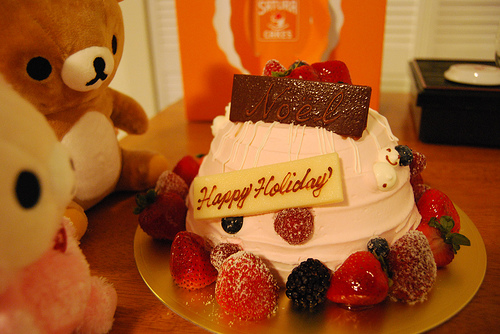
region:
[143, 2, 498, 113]
white painted louvered doors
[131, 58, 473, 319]
cake decorated for Christmas holiday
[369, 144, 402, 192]
smiley faced snow man decoration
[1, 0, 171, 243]
brown and white stuffed teddy bear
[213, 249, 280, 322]
piece of sugar sprinkled strawberry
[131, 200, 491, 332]
gold colored cake plate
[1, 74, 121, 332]
pink and white stuffed animal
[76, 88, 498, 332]
wood grained table top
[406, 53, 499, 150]
small wooden box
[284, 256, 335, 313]
black berry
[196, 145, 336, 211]
yellow sign on cake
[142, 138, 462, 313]
berries all around cake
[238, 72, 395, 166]
brown sign on cake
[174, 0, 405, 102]
orange sign behind cake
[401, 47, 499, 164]
brown table in background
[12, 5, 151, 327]
teddy bears around cake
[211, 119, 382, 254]
white icing on cake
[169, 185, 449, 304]
berries on platter are sugared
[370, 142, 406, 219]
snowman decoration on cake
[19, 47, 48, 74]
bear has small black eyes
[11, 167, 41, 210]
Black eye on a white and pink stuffed animal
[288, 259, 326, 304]
Blackberry at the bottom of a cake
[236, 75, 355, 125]
Thin piece of chocolate with "Noel" on it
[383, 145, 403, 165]
Red and white snowman decoration on a holiday cake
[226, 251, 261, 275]
The top of a red strawberry sprinkled with sugar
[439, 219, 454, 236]
The leafy green stem of a strawberry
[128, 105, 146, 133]
The brown paw of a stuffed teddy bear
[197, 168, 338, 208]
A thin rectangle of white chocolate with "Happy Holiday" in red icing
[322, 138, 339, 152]
Thin white drizzles of icing on a cake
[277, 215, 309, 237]
A red raspberry covered with sugar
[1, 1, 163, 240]
a brown teddy bear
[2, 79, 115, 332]
a pink teddy bear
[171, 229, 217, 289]
a ripe red strawberry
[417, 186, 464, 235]
a ripe red strawberry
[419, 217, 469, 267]
a ripe red strawberry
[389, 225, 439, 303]
a sugared red strawberry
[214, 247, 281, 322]
a sugared red strawberry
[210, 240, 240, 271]
a sugared red strawberry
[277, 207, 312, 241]
a sugared red strawberry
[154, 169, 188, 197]
a sugared red strawberry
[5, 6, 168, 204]
The bear is brown.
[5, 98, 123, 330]
The bear is pink.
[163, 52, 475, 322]
The cake is on a platter.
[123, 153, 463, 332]
The platter is gold.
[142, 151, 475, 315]
The strawberries are red.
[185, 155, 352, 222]
The wording is brown.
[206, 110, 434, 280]
The frosting is pink.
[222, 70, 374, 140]
The chocolate is on top of the cake.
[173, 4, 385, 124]
The box is orange.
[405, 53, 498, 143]
The box is black.